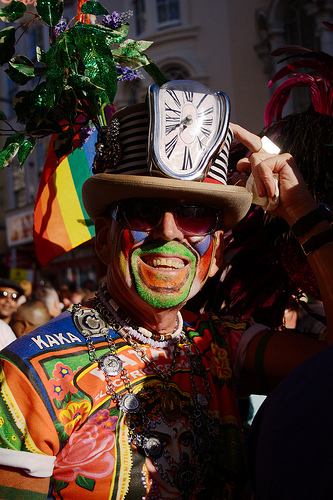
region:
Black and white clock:
[162, 83, 240, 210]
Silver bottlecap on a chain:
[70, 301, 110, 344]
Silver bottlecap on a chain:
[92, 349, 121, 377]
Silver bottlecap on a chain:
[106, 394, 150, 409]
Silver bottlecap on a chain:
[132, 436, 164, 462]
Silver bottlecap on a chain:
[186, 379, 214, 412]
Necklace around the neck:
[91, 278, 197, 366]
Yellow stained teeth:
[160, 257, 178, 269]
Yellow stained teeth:
[148, 257, 159, 267]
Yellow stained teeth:
[173, 258, 183, 267]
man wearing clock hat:
[156, 79, 228, 179]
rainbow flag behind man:
[35, 122, 95, 261]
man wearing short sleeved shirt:
[1, 303, 271, 497]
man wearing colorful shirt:
[1, 296, 263, 498]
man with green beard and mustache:
[130, 240, 195, 305]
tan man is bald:
[6, 297, 47, 337]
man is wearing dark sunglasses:
[0, 289, 17, 298]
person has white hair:
[37, 285, 59, 317]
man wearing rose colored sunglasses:
[107, 200, 223, 233]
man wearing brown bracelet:
[284, 204, 331, 238]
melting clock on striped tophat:
[82, 82, 260, 212]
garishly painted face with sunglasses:
[94, 198, 231, 310]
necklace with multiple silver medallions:
[60, 299, 236, 486]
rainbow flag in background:
[37, 85, 97, 267]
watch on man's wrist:
[290, 215, 329, 273]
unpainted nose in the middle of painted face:
[155, 206, 184, 245]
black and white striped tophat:
[77, 105, 272, 222]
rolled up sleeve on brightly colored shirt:
[1, 442, 54, 475]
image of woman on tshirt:
[84, 380, 201, 495]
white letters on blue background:
[27, 332, 83, 352]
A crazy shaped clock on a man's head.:
[149, 77, 223, 175]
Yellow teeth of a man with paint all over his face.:
[144, 255, 186, 268]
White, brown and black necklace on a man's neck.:
[99, 281, 182, 340]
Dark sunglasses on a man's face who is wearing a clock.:
[104, 200, 226, 233]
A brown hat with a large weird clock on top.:
[82, 78, 253, 231]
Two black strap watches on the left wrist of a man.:
[288, 202, 332, 256]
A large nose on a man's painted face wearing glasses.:
[152, 211, 184, 241]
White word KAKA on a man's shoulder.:
[29, 333, 81, 349]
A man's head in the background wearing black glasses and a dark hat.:
[0, 277, 25, 322]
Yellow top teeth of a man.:
[146, 257, 184, 268]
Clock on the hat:
[145, 87, 241, 157]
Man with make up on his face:
[111, 210, 216, 307]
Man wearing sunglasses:
[117, 197, 223, 239]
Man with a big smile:
[130, 240, 207, 275]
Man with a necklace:
[69, 316, 243, 473]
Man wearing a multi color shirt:
[22, 320, 222, 496]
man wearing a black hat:
[10, 274, 21, 298]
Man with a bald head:
[13, 300, 46, 329]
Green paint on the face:
[147, 247, 206, 311]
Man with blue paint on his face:
[124, 222, 222, 258]